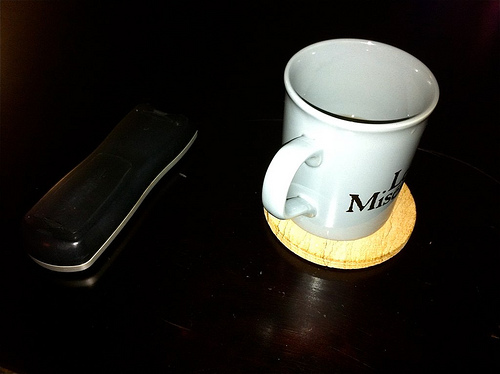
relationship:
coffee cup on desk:
[261, 38, 440, 241] [262, 39, 439, 244]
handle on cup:
[262, 136, 323, 220] [225, 15, 448, 276]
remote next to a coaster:
[22, 105, 198, 272] [256, 174, 423, 284]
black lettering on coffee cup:
[347, 164, 409, 212] [261, 38, 440, 241]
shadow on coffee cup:
[293, 93, 415, 123] [261, 38, 440, 241]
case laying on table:
[33, 69, 255, 304] [1, 1, 498, 372]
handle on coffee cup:
[262, 136, 323, 220] [258, 34, 440, 244]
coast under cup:
[263, 181, 417, 269] [224, 19, 420, 240]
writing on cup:
[344, 170, 409, 214] [211, 67, 397, 329]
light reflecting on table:
[287, 273, 341, 330] [1, 1, 498, 372]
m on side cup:
[348, 187, 383, 221] [256, 25, 458, 260]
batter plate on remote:
[30, 161, 138, 239] [30, 95, 210, 278]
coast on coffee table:
[263, 181, 417, 269] [1, 0, 499, 372]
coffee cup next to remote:
[261, 38, 440, 241] [22, 105, 198, 272]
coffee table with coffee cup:
[1, 0, 499, 372] [261, 38, 440, 241]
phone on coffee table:
[31, 85, 219, 302] [1, 0, 499, 372]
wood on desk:
[240, 305, 492, 365] [1, 0, 498, 373]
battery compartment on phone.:
[38, 153, 133, 237] [24, 74, 224, 260]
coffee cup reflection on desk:
[261, 38, 440, 241] [1, 0, 498, 373]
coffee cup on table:
[261, 38, 440, 241] [1, 1, 498, 372]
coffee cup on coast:
[261, 38, 440, 241] [263, 181, 419, 267]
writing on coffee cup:
[393, 188, 400, 200] [261, 38, 440, 241]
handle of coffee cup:
[262, 136, 323, 220] [261, 38, 440, 241]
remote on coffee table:
[30, 95, 210, 278] [1, 0, 499, 372]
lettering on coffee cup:
[349, 167, 405, 212] [261, 38, 440, 241]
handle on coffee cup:
[258, 118, 328, 222] [261, 38, 440, 241]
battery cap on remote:
[31, 137, 138, 243] [13, 45, 231, 326]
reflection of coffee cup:
[268, 270, 342, 360] [261, 38, 440, 241]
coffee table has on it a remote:
[1, 0, 499, 372] [22, 105, 207, 291]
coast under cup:
[263, 181, 417, 269] [242, 35, 442, 264]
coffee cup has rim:
[261, 38, 440, 241] [282, 35, 439, 132]